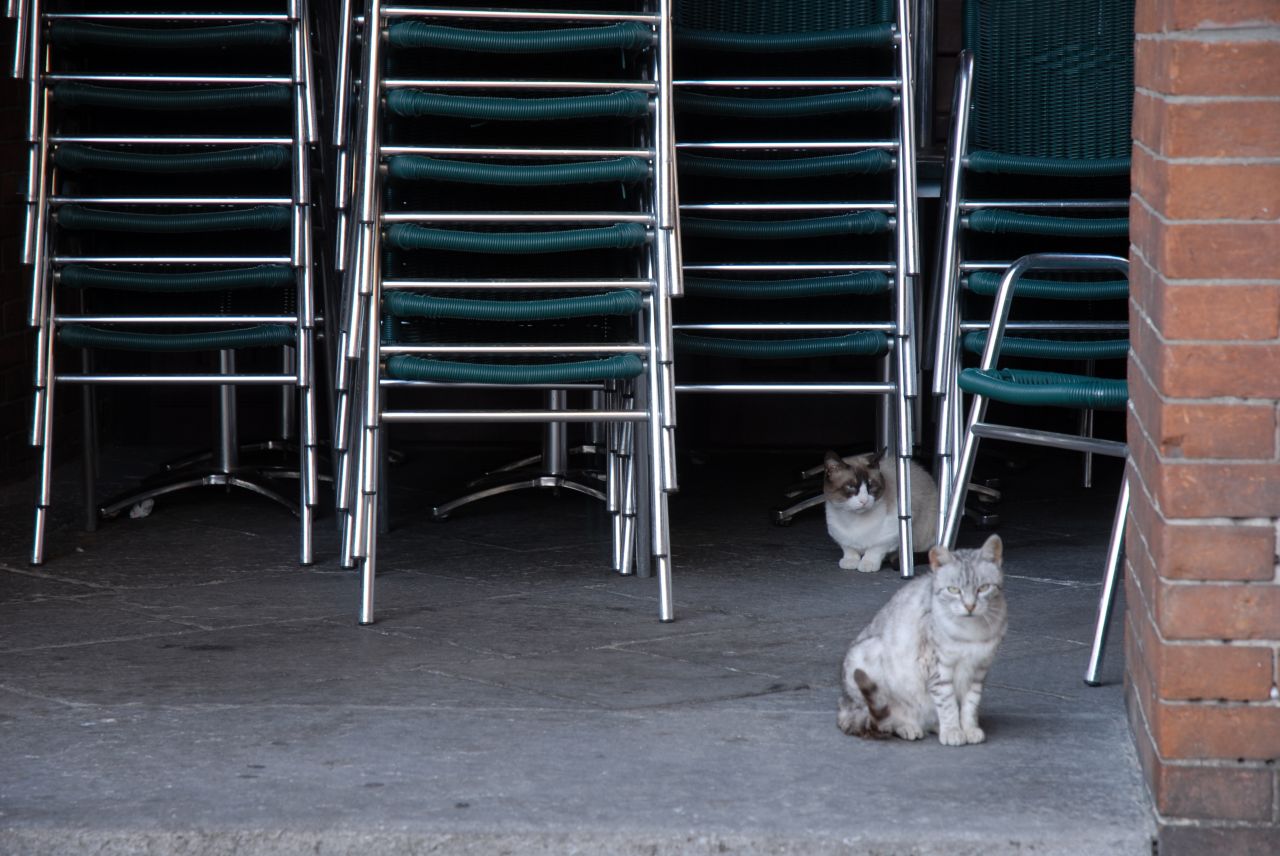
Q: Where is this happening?
A: In front of chairs.